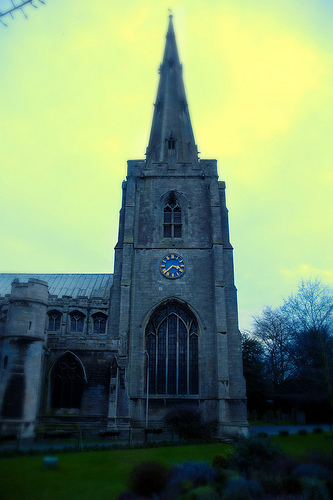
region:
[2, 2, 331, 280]
a yellow glow surrounds the church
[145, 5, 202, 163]
small windows dot the church steeple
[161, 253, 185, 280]
a blue faced clock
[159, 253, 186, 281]
clock has gold roman numerals and hands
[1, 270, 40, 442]
a shorter tower on side of church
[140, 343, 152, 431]
a drain pipe in front of stained glass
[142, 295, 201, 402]
large arched stained glass window under steeple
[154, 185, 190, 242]
two windows with a round window on top is centered below the steeple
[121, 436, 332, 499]
bushes landscape the foreground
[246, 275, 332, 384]
trees have lost leaves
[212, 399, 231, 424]
large concrete block on tower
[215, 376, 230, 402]
large concrete block on tower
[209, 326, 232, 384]
large concrete block on tower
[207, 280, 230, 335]
large concrete block on tower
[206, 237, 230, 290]
large concrete block on tower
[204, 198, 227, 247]
large concrete block on tower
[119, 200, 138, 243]
large concrete block on tower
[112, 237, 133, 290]
large concrete block on tower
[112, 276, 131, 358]
large concrete block on tower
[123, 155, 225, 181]
large concrete block on tower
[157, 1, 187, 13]
top of building has statue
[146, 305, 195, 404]
arched glass windows in the front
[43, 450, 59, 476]
blue item on the ground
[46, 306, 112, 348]
three windows on the top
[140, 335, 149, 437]
light post in front of building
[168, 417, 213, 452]
bush next to building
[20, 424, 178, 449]
gate surrounding the building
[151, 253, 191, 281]
numbers on clock in roman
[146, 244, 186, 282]
time is 3:43pm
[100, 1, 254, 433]
tan clock tower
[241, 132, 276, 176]
white clouds in blue sky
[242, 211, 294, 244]
white clouds in blue sky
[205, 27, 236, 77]
white clouds in blue sky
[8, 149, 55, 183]
white clouds in blue sky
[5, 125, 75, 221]
white clouds in blue sky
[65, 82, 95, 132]
white clouds in blue sky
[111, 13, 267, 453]
this is a tower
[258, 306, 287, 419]
this is a tree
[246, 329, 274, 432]
this is a tree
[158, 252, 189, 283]
this is a clock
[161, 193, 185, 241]
this is a window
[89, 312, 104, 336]
this is a window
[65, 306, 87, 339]
this is a window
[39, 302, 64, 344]
this is a window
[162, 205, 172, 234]
building has a window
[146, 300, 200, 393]
building has a window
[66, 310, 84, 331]
building has a window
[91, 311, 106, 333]
building has a window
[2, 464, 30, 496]
a green trimmed patch of grass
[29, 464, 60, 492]
a green trimmed patch of grass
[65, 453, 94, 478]
a green trimmed patch of grass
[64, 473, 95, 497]
a green trimmed patch of grass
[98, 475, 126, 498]
a green trimmed patch of grass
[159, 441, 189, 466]
a green trimmed patch of grass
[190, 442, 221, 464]
a green trimmed patch of grass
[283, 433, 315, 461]
a green trimmed patch of grass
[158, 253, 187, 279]
round blue clock face with yellow numerals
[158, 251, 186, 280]
round blue clock face with yellow hands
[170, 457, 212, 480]
small blue bush on green grass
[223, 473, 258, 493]
small blue bush on green grass